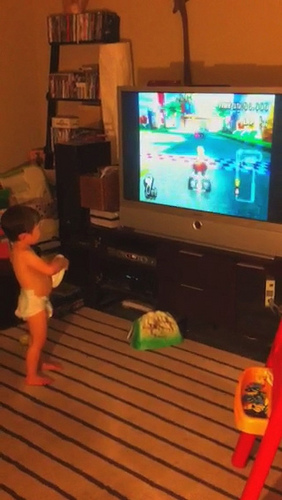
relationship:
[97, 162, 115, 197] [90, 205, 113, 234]
box sitting upon stack of books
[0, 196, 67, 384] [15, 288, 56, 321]
baby in diapers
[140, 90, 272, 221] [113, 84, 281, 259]
screen of television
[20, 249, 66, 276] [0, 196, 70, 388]
arm of baby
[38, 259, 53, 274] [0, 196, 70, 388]
elbow of baby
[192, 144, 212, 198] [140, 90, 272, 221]
character on screen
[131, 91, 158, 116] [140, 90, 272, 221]
corner on screen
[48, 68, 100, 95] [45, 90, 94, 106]
items on shelf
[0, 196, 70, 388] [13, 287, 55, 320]
baby in diaper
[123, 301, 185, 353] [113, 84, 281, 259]
item under television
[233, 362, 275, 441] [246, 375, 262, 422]
tray holding toys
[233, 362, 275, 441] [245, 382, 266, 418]
tray holding toys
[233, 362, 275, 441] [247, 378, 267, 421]
tray holding toys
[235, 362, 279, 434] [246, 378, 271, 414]
tray holding toys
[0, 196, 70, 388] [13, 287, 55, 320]
baby wearing diaper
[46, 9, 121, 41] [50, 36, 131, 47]
movies on top of shelf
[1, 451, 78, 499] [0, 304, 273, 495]
sripe on carpet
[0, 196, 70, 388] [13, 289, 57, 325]
baby on pamper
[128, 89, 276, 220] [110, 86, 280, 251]
game on screen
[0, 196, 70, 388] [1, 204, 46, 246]
baby has head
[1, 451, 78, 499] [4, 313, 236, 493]
sripe on floor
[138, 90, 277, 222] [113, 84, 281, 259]
screen on television